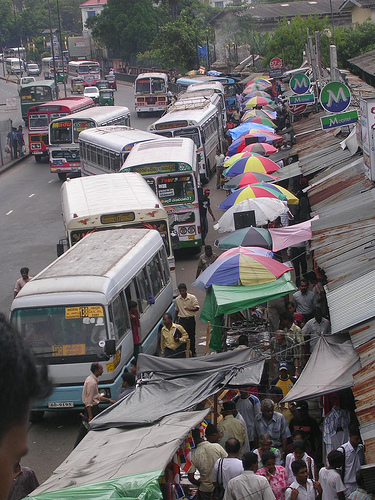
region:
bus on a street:
[25, 275, 116, 335]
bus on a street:
[60, 169, 112, 223]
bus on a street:
[168, 147, 201, 242]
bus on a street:
[167, 98, 217, 129]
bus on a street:
[42, 118, 75, 165]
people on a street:
[226, 420, 319, 491]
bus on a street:
[130, 62, 167, 110]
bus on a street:
[66, 55, 103, 75]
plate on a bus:
[47, 398, 77, 411]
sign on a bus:
[96, 208, 138, 226]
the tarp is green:
[223, 288, 245, 305]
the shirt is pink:
[267, 473, 284, 486]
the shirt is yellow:
[165, 330, 177, 349]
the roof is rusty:
[357, 371, 371, 395]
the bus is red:
[59, 100, 75, 116]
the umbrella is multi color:
[241, 185, 258, 196]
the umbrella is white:
[251, 200, 272, 216]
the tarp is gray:
[146, 386, 167, 404]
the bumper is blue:
[60, 388, 78, 400]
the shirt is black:
[201, 198, 210, 209]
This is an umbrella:
[195, 250, 306, 288]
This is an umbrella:
[206, 241, 291, 257]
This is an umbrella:
[219, 221, 319, 249]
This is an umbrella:
[218, 193, 319, 224]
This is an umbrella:
[225, 179, 313, 196]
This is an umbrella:
[221, 165, 307, 189]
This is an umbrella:
[223, 149, 288, 183]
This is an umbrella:
[233, 117, 294, 158]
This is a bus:
[32, 226, 199, 414]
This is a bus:
[73, 164, 225, 251]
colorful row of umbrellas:
[187, 69, 303, 318]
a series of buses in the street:
[3, 76, 225, 395]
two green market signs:
[276, 64, 361, 133]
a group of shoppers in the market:
[172, 376, 361, 492]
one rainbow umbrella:
[194, 247, 298, 288]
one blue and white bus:
[8, 227, 190, 411]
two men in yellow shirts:
[155, 281, 201, 358]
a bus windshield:
[8, 307, 113, 358]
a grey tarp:
[28, 402, 210, 493]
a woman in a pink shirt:
[254, 444, 291, 498]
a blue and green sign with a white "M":
[316, 79, 349, 111]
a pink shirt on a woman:
[255, 460, 287, 494]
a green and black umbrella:
[210, 222, 273, 243]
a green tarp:
[191, 270, 293, 326]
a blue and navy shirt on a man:
[267, 371, 297, 401]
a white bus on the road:
[14, 223, 188, 427]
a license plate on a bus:
[47, 398, 74, 411]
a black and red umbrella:
[219, 168, 275, 192]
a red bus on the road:
[22, 91, 92, 169]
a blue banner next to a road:
[194, 41, 210, 60]